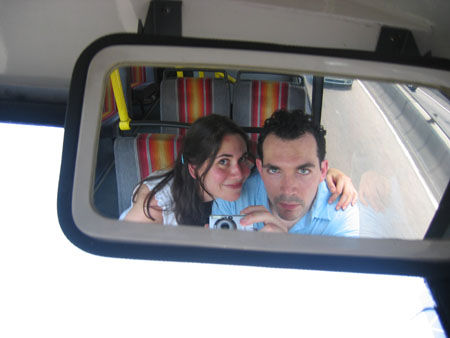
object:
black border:
[57, 32, 450, 278]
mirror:
[91, 63, 449, 242]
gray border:
[71, 44, 449, 262]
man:
[206, 109, 361, 237]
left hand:
[240, 204, 289, 233]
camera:
[208, 214, 254, 231]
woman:
[119, 115, 358, 228]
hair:
[132, 113, 257, 226]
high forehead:
[260, 129, 318, 169]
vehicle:
[307, 74, 353, 87]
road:
[304, 73, 440, 241]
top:
[118, 167, 181, 227]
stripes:
[177, 75, 213, 134]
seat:
[160, 67, 230, 134]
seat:
[232, 69, 308, 154]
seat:
[112, 119, 192, 218]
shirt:
[212, 167, 359, 238]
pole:
[110, 68, 131, 131]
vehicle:
[0, 0, 449, 338]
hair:
[257, 109, 327, 171]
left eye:
[297, 167, 311, 175]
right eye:
[267, 168, 281, 175]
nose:
[280, 169, 297, 195]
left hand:
[325, 165, 358, 211]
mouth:
[278, 200, 301, 209]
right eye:
[216, 158, 230, 166]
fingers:
[253, 221, 286, 233]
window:
[304, 74, 449, 238]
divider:
[360, 78, 450, 201]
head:
[181, 113, 250, 201]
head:
[255, 108, 328, 221]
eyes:
[239, 156, 246, 164]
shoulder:
[318, 180, 359, 237]